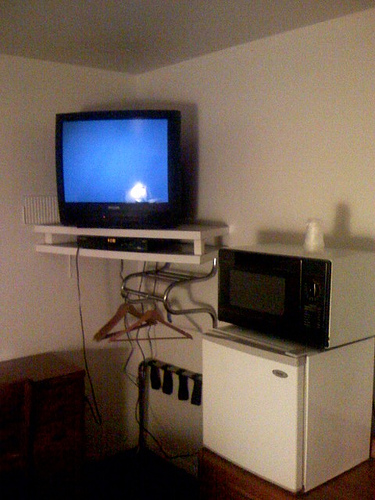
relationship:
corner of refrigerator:
[359, 446, 373, 467] [180, 293, 335, 498]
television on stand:
[53, 111, 186, 231] [19, 206, 228, 274]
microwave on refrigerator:
[213, 245, 374, 351] [195, 289, 372, 491]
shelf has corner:
[35, 224, 231, 264] [191, 230, 207, 264]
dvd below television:
[82, 237, 164, 251] [52, 105, 190, 227]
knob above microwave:
[308, 281, 319, 299] [215, 245, 374, 347]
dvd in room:
[76, 237, 163, 251] [1, 1, 362, 498]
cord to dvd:
[75, 243, 102, 425] [76, 237, 163, 251]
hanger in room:
[85, 277, 206, 364] [1, 1, 362, 498]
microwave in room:
[215, 245, 374, 347] [1, 1, 362, 498]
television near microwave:
[53, 111, 186, 231] [217, 245, 350, 346]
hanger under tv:
[105, 294, 195, 347] [44, 102, 195, 237]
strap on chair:
[186, 372, 204, 410] [112, 342, 200, 470]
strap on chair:
[173, 361, 192, 405] [112, 342, 200, 470]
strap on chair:
[158, 361, 175, 396] [112, 342, 200, 470]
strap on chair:
[143, 356, 164, 392] [112, 342, 200, 470]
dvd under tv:
[76, 237, 163, 251] [53, 99, 183, 229]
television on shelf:
[53, 111, 186, 231] [35, 224, 231, 264]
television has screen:
[40, 101, 190, 231] [57, 119, 170, 203]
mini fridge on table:
[199, 322, 374, 496] [196, 447, 374, 498]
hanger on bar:
[91, 286, 157, 342] [123, 286, 164, 302]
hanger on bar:
[107, 293, 192, 342] [123, 286, 164, 302]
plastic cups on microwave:
[299, 215, 326, 258] [215, 245, 374, 347]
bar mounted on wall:
[118, 257, 218, 329] [135, 1, 373, 469]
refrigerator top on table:
[187, 318, 368, 487] [195, 447, 374, 499]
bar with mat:
[134, 357, 196, 471] [25, 428, 236, 498]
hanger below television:
[105, 294, 195, 347] [19, 91, 202, 237]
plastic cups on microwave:
[299, 215, 325, 253] [215, 245, 374, 347]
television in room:
[53, 111, 186, 231] [1, 1, 362, 498]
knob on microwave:
[308, 281, 319, 299] [204, 227, 373, 361]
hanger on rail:
[105, 294, 195, 347] [119, 269, 187, 314]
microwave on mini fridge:
[215, 245, 374, 347] [197, 322, 374, 498]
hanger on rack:
[105, 294, 195, 347] [119, 268, 222, 336]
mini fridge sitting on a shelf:
[197, 322, 374, 498] [30, 220, 220, 277]